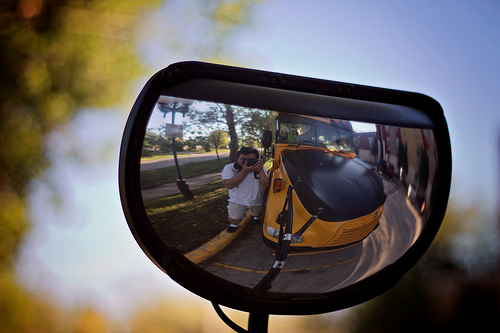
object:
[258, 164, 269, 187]
arm of a person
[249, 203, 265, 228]
leg of a person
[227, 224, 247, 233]
feet of a person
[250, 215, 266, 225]
feet of a person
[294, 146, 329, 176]
reflection in mirror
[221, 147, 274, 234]
adult male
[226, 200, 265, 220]
cargo shorts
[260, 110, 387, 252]
yellow curb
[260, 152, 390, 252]
end of yellow bus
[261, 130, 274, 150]
black mirror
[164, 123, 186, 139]
sign on pole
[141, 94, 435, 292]
picture in mirror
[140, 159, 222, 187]
grass growing on med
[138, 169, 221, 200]
edge of median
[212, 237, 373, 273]
yellow lines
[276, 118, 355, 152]
windshield of bus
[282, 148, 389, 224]
hood of bus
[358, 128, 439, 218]
trees near building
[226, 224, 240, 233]
black shoes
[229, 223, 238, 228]
man wearing socks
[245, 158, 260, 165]
black camera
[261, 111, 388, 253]
bus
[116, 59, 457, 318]
mirror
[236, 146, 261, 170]
head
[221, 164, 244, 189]
arm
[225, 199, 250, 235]
leg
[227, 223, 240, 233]
foot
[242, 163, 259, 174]
hand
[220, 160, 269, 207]
shirt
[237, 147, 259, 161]
hair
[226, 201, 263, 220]
shorts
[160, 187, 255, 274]
concrete